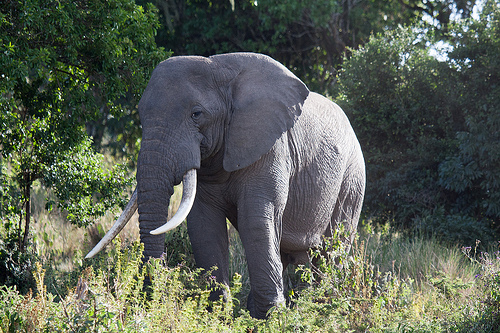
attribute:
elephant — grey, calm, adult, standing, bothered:
[81, 51, 366, 320]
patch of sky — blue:
[406, 1, 499, 67]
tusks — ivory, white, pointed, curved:
[83, 168, 196, 261]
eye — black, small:
[189, 109, 205, 120]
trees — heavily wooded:
[0, 2, 495, 241]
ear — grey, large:
[210, 51, 311, 174]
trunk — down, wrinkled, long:
[136, 121, 178, 301]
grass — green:
[1, 155, 496, 331]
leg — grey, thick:
[235, 191, 285, 321]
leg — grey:
[186, 183, 235, 312]